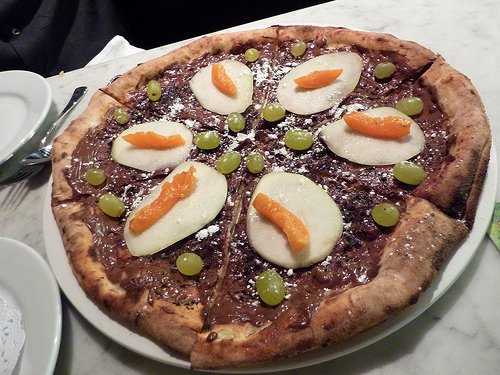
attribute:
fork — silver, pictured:
[3, 84, 88, 182]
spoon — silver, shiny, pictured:
[22, 74, 121, 159]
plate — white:
[1, 237, 64, 375]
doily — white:
[1, 295, 27, 374]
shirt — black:
[1, 4, 141, 75]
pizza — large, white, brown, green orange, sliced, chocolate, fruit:
[50, 23, 499, 356]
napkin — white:
[81, 32, 142, 69]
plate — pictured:
[2, 71, 54, 175]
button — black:
[10, 28, 23, 38]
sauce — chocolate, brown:
[69, 39, 456, 331]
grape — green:
[371, 59, 397, 81]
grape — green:
[394, 94, 425, 120]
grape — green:
[387, 162, 427, 190]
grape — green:
[254, 269, 283, 312]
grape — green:
[367, 199, 401, 230]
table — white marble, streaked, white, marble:
[1, 0, 497, 374]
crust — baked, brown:
[48, 23, 494, 375]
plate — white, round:
[43, 24, 497, 373]